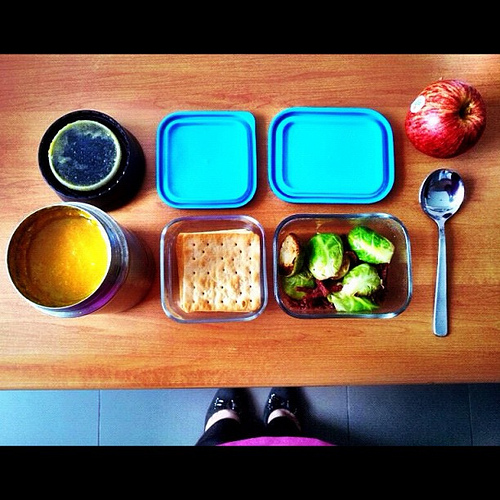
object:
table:
[1, 51, 500, 392]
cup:
[7, 202, 155, 319]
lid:
[47, 118, 123, 191]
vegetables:
[283, 226, 394, 313]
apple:
[403, 78, 487, 159]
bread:
[175, 229, 262, 314]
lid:
[155, 111, 257, 207]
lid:
[268, 106, 395, 205]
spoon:
[418, 168, 466, 338]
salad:
[278, 225, 395, 311]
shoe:
[204, 386, 245, 429]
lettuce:
[347, 224, 395, 264]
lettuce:
[306, 232, 343, 280]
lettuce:
[327, 263, 384, 313]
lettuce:
[283, 270, 315, 301]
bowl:
[158, 213, 269, 323]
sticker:
[410, 95, 425, 113]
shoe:
[264, 386, 301, 427]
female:
[194, 385, 338, 447]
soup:
[20, 218, 109, 303]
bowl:
[271, 210, 412, 321]